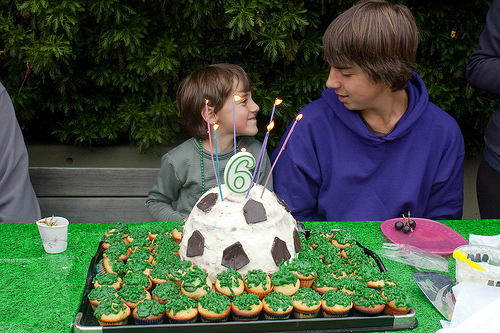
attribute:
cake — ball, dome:
[179, 183, 300, 272]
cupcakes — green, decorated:
[87, 229, 413, 315]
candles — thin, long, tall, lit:
[203, 95, 303, 199]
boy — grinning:
[144, 61, 273, 220]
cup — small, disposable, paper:
[34, 215, 69, 252]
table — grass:
[1, 220, 498, 332]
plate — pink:
[375, 214, 468, 255]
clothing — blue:
[273, 70, 465, 219]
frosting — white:
[182, 184, 300, 273]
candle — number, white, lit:
[223, 148, 256, 192]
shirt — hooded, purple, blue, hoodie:
[273, 73, 465, 219]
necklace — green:
[196, 137, 208, 192]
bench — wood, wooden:
[28, 168, 157, 223]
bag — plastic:
[381, 239, 449, 275]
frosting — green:
[90, 227, 409, 317]